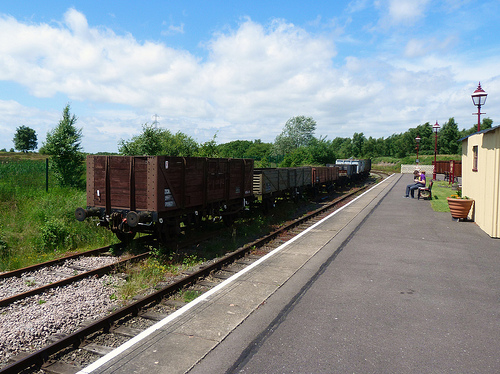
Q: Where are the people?
A: On the platform.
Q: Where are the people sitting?
A: On the bench.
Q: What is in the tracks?
A: Cargo train.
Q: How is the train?
A: Parked.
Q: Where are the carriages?
A: On train.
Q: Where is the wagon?
A: On train.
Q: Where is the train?
A: On tracks.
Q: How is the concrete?
A: Painted.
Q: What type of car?
A: Train.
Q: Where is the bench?
A: On platform.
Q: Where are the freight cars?
A: On the tracks.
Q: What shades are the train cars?
A: Rusty brown, grey, red and light blue.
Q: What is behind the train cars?
A: Small trees and bushes.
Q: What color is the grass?
A: Green.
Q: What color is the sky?
A: Blue.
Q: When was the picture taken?
A: Daytime.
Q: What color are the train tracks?
A: Brown.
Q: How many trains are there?
A: One.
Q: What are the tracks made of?
A: Metal.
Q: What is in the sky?
A: Clouds.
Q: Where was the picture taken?
A: Near tracks.